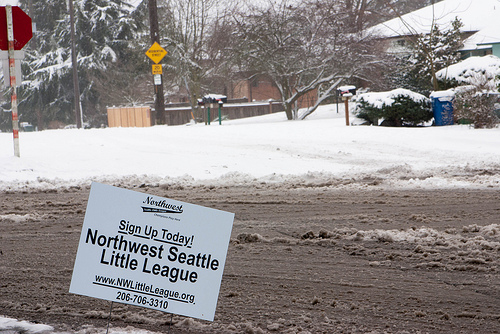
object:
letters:
[84, 220, 219, 283]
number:
[115, 291, 168, 309]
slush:
[321, 221, 500, 259]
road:
[0, 191, 498, 333]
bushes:
[351, 87, 436, 126]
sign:
[144, 41, 167, 64]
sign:
[0, 6, 33, 50]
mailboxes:
[198, 94, 228, 126]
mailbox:
[338, 85, 356, 126]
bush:
[451, 85, 499, 128]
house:
[347, 0, 500, 91]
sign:
[70, 181, 237, 323]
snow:
[0, 127, 500, 178]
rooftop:
[358, 0, 499, 51]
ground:
[1, 129, 498, 334]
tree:
[0, 0, 187, 125]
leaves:
[88, 15, 115, 41]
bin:
[432, 91, 454, 126]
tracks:
[0, 185, 500, 226]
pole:
[4, 4, 19, 156]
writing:
[117, 214, 196, 247]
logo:
[140, 196, 184, 222]